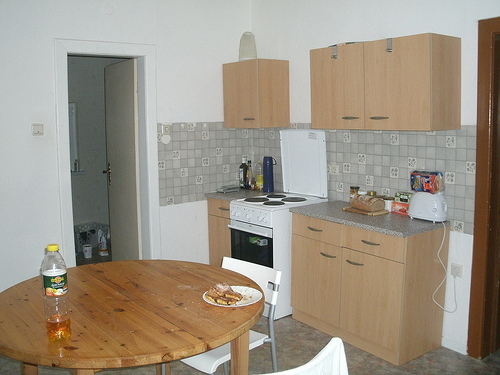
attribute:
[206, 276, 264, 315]
plate — white, round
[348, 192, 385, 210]
bread — brown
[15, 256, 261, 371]
table — wooden, round, brown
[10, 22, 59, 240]
wall — white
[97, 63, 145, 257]
door — open, beige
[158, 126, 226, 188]
tiles — gray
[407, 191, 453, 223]
toaster — white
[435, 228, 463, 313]
cord — plugged in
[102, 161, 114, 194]
doorknob — gold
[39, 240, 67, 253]
top — yellow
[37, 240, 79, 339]
bottle — plastic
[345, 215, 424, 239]
counter — gray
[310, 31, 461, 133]
cabinets — high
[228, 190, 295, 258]
stove — white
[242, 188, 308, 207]
burners — black, round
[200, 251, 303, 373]
chair — white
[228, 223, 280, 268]
oven door — black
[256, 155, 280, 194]
thermos — blue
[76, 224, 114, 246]
basket — gray